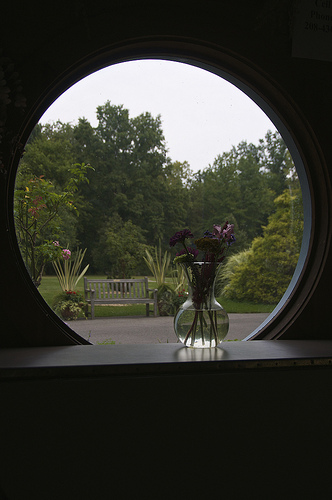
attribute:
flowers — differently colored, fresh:
[169, 218, 236, 348]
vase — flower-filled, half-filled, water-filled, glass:
[174, 262, 230, 349]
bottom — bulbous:
[174, 299, 230, 350]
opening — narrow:
[182, 259, 220, 269]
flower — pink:
[207, 220, 234, 245]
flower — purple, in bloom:
[169, 229, 193, 252]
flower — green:
[174, 253, 194, 265]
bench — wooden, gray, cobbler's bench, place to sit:
[80, 278, 159, 319]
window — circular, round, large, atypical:
[15, 57, 312, 340]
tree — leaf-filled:
[12, 120, 92, 286]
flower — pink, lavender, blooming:
[60, 249, 70, 259]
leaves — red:
[27, 195, 46, 216]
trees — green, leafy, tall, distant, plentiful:
[16, 101, 297, 277]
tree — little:
[90, 210, 165, 290]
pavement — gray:
[62, 311, 270, 345]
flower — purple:
[177, 247, 200, 257]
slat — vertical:
[126, 281, 134, 300]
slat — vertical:
[97, 282, 100, 298]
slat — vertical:
[101, 282, 105, 301]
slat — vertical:
[106, 282, 110, 299]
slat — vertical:
[140, 280, 143, 298]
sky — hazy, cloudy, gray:
[37, 59, 297, 190]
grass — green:
[41, 274, 278, 317]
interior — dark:
[0, 1, 329, 499]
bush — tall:
[221, 186, 302, 300]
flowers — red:
[65, 290, 76, 296]